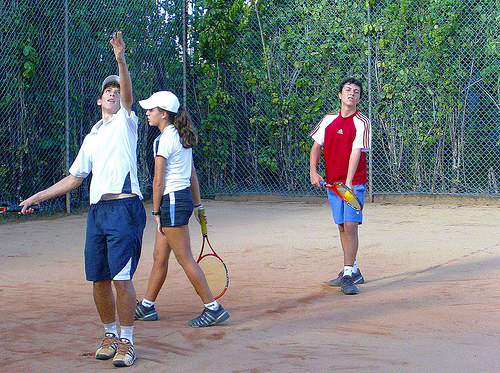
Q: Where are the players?
A: In the court.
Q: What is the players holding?
A: Rackets.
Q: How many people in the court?
A: Three.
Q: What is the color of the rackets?
A: Red.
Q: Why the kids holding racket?
A: To play.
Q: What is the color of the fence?
A: Blue.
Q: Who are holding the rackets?
A: Kids.